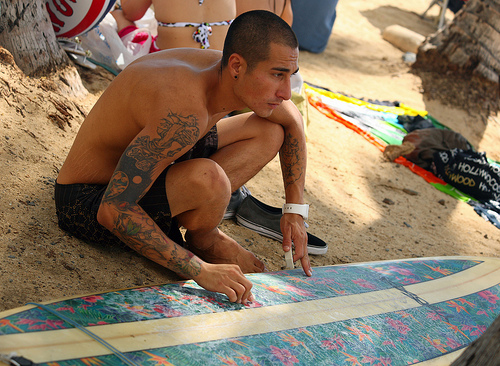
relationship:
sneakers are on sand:
[217, 183, 249, 221] [1, 1, 497, 308]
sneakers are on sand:
[235, 190, 328, 255] [1, 1, 497, 308]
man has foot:
[51, 8, 313, 303] [199, 231, 249, 280]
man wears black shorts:
[51, 8, 313, 303] [53, 120, 220, 253]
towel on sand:
[303, 81, 498, 228] [308, 124, 489, 254]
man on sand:
[51, 8, 313, 303] [1, 1, 497, 308]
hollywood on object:
[454, 160, 499, 195] [435, 141, 499, 203]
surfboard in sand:
[5, 238, 499, 364] [9, 180, 499, 293]